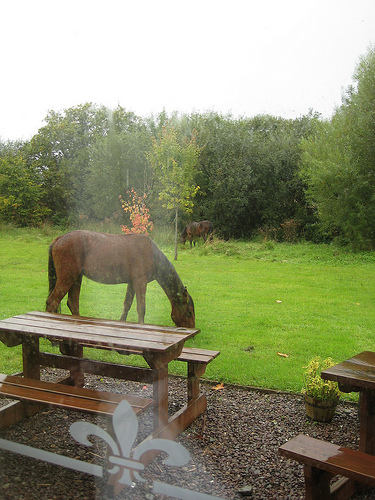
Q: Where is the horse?
A: Backyard.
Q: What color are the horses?
A: Brown.